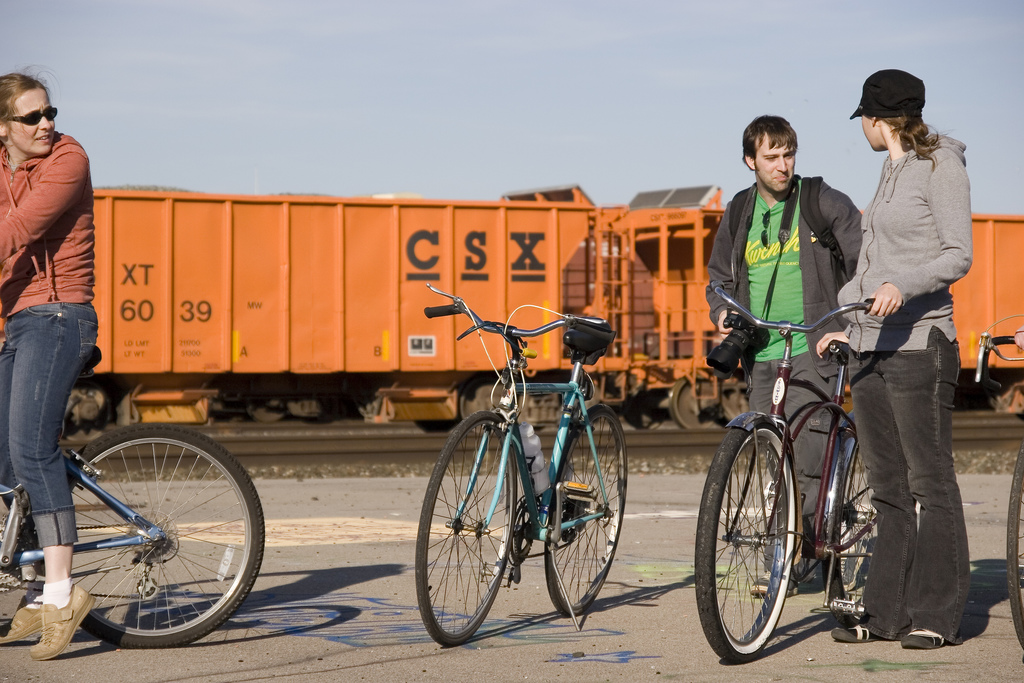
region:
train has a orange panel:
[346, 205, 397, 376]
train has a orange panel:
[286, 205, 341, 370]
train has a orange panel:
[115, 198, 166, 369]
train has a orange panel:
[89, 201, 105, 366]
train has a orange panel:
[396, 210, 447, 370]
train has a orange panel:
[444, 205, 502, 365]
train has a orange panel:
[500, 210, 549, 366]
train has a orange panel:
[559, 213, 594, 366]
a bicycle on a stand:
[413, 277, 633, 645]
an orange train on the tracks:
[120, 180, 646, 463]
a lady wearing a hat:
[838, 51, 965, 296]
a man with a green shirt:
[705, 119, 848, 350]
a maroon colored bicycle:
[695, 282, 911, 679]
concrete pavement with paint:
[300, 566, 399, 666]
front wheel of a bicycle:
[411, 411, 525, 645]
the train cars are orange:
[52, 165, 743, 454]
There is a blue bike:
[381, 282, 635, 652]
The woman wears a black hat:
[838, 63, 950, 156]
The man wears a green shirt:
[724, 123, 832, 430]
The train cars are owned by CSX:
[377, 202, 562, 289]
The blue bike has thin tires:
[393, 372, 530, 651]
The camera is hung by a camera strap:
[713, 120, 806, 345]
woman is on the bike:
[0, 73, 263, 659]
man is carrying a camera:
[707, 171, 806, 365]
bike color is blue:
[414, 290, 629, 658]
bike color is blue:
[6, 345, 269, 669]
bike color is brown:
[702, 277, 902, 660]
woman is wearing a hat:
[849, 68, 925, 120]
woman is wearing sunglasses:
[6, 105, 61, 132]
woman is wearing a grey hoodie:
[843, 124, 974, 340]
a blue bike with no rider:
[424, 278, 650, 634]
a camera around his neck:
[699, 170, 795, 373]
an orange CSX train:
[85, 183, 1021, 411]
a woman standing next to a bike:
[809, 60, 1002, 656]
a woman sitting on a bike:
[0, 69, 128, 651]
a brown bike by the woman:
[699, 281, 881, 670]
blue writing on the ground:
[246, 552, 651, 680]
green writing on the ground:
[632, 537, 731, 608]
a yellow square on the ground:
[100, 480, 492, 570]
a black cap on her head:
[849, 66, 920, 128]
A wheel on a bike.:
[411, 412, 525, 646]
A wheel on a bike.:
[544, 399, 653, 608]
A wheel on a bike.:
[688, 421, 791, 657]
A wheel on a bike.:
[814, 409, 928, 634]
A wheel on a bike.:
[43, 435, 299, 651]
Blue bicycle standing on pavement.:
[412, 280, 629, 642]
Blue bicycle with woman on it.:
[0, 418, 261, 643]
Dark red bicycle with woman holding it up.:
[691, 270, 869, 656]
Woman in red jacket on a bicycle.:
[0, 57, 81, 646]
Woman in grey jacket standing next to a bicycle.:
[813, 65, 972, 647]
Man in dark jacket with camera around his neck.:
[704, 114, 864, 595]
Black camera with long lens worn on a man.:
[706, 311, 767, 372]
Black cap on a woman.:
[848, 65, 926, 119]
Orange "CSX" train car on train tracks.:
[74, 182, 625, 418]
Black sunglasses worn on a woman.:
[2, 104, 60, 127]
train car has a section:
[348, 206, 391, 361]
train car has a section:
[403, 204, 449, 366]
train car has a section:
[508, 201, 554, 357]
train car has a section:
[557, 210, 590, 353]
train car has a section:
[110, 192, 171, 367]